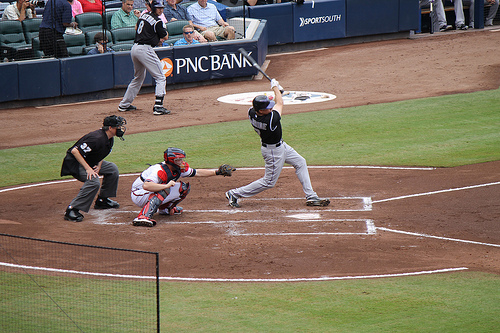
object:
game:
[8, 66, 488, 333]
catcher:
[128, 144, 240, 232]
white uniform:
[128, 162, 198, 214]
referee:
[56, 110, 128, 223]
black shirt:
[59, 127, 118, 168]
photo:
[3, 3, 495, 332]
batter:
[223, 75, 331, 210]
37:
[76, 139, 94, 156]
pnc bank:
[173, 45, 263, 75]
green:
[3, 91, 499, 331]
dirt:
[0, 26, 500, 286]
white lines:
[0, 258, 472, 284]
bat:
[236, 47, 287, 95]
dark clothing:
[60, 127, 125, 212]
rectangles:
[222, 216, 380, 239]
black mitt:
[216, 162, 238, 177]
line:
[370, 178, 499, 206]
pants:
[231, 142, 323, 199]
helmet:
[248, 92, 276, 117]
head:
[251, 94, 277, 116]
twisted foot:
[305, 196, 331, 207]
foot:
[223, 190, 245, 209]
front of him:
[183, 154, 239, 180]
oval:
[0, 161, 469, 289]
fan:
[172, 23, 201, 47]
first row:
[30, 20, 197, 59]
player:
[113, 0, 173, 118]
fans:
[185, 0, 238, 44]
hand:
[85, 168, 103, 180]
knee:
[81, 171, 107, 189]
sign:
[156, 50, 256, 79]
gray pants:
[67, 156, 120, 214]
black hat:
[100, 112, 128, 129]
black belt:
[261, 138, 285, 148]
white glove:
[270, 78, 280, 90]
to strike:
[226, 37, 296, 143]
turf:
[3, 158, 499, 284]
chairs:
[58, 32, 90, 57]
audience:
[83, 33, 119, 55]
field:
[3, 31, 497, 331]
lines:
[235, 196, 370, 202]